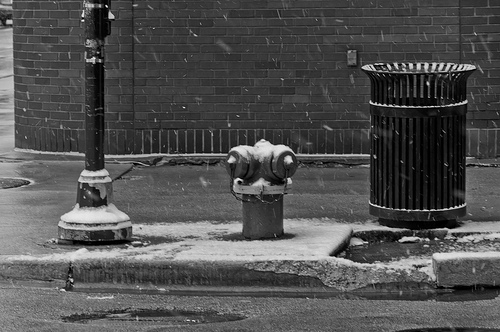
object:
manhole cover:
[2, 160, 46, 202]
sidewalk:
[148, 160, 220, 213]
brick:
[208, 37, 328, 93]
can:
[190, 49, 499, 250]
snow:
[52, 169, 134, 230]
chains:
[231, 184, 291, 201]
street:
[8, 285, 495, 330]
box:
[343, 47, 360, 67]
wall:
[8, 2, 498, 158]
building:
[11, 3, 498, 231]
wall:
[193, 37, 310, 117]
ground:
[370, 70, 442, 108]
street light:
[57, 2, 132, 274]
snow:
[59, 202, 132, 240]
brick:
[212, 85, 244, 95]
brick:
[248, 92, 284, 100]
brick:
[295, 65, 324, 78]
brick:
[270, 30, 310, 45]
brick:
[215, 25, 254, 36]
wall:
[112, 21, 167, 131]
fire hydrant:
[220, 133, 310, 256]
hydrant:
[224, 134, 296, 247]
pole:
[50, 2, 135, 167]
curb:
[5, 241, 498, 296]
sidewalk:
[5, 157, 364, 264]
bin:
[350, 40, 482, 237]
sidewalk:
[1, 165, 498, 216]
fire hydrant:
[222, 137, 298, 241]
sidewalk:
[1, 154, 498, 262]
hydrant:
[252, 200, 276, 232]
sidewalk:
[172, 179, 218, 214]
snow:
[174, 237, 332, 267]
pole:
[56, 3, 135, 246]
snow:
[193, 197, 348, 274]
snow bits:
[109, 18, 354, 181]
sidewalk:
[4, 151, 497, 317]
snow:
[45, 213, 499, 270]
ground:
[3, 147, 498, 329]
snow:
[224, 139, 293, 251]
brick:
[227, 66, 271, 80]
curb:
[1, 223, 496, 320]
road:
[10, 280, 499, 330]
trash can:
[356, 51, 466, 241]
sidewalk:
[45, 290, 370, 324]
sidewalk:
[28, 121, 480, 307]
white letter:
[298, 227, 341, 257]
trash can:
[312, 38, 487, 232]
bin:
[359, 58, 477, 189]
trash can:
[342, 50, 484, 232]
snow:
[72, 155, 394, 311]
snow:
[229, 136, 292, 161]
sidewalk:
[123, 165, 217, 237]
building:
[19, 16, 331, 141]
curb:
[1, 249, 202, 292]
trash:
[361, 49, 478, 209]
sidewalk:
[146, 223, 461, 330]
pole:
[34, 62, 142, 253]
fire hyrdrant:
[175, 122, 332, 304]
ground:
[145, 223, 248, 295]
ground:
[148, 288, 419, 319]